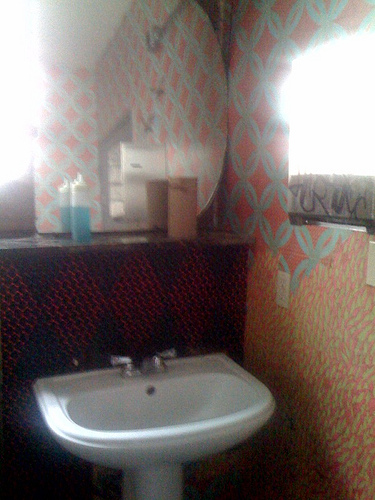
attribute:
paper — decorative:
[232, 7, 365, 484]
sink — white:
[16, 347, 290, 500]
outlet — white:
[272, 261, 297, 316]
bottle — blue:
[61, 167, 100, 244]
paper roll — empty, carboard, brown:
[162, 167, 209, 250]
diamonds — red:
[129, 46, 225, 133]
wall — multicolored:
[276, 221, 367, 499]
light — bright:
[278, 35, 374, 167]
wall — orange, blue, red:
[210, 9, 286, 234]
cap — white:
[112, 132, 178, 186]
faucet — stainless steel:
[137, 348, 174, 378]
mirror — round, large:
[42, 2, 244, 227]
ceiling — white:
[35, 1, 129, 71]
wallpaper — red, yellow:
[209, 6, 374, 386]